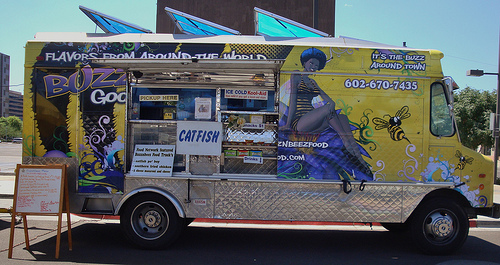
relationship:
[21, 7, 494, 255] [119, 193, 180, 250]
truck has a rear wheel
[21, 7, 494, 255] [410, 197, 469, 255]
truck has a front wheel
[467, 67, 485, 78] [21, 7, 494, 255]
lamp by truck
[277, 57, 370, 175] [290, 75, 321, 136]
woman in a swimsuit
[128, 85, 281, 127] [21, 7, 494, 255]
side window on a truck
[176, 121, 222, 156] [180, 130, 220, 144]
sign with writing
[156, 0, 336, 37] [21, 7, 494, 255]
building behind truck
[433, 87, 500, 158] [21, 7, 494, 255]
trees behind truck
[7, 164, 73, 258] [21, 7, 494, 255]
menu board next to truck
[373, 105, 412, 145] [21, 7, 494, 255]
bee on a truck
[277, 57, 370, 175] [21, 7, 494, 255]
woman painted on truck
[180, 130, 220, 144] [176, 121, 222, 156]
writing on a sign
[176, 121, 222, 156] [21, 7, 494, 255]
sign on a truck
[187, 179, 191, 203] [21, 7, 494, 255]
strap on side of truck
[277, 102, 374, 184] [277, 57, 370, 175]
flower below woman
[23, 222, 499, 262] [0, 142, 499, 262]
shadow on ground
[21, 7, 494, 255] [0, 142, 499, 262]
truck parked on ground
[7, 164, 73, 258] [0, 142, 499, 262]
menu board on ground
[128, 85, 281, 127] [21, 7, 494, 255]
side window on truck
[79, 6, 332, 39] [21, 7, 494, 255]
vent on truck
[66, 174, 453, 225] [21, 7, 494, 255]
panel on truck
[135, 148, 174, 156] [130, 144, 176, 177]
lower writing on lower sign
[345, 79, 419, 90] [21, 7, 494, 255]
phone number on truck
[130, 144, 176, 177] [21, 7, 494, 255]
lower sign on truck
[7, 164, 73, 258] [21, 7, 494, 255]
menu board by truck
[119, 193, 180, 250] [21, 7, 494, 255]
rear wheel of truck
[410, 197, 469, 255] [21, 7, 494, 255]
front wheel of truck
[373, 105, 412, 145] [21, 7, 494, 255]
bee on truck